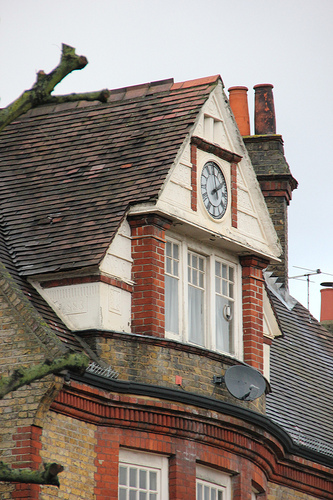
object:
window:
[164, 235, 185, 343]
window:
[195, 475, 226, 499]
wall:
[70, 285, 131, 329]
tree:
[0, 39, 89, 498]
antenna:
[287, 269, 322, 313]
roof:
[264, 288, 333, 459]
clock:
[199, 158, 230, 223]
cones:
[227, 85, 250, 135]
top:
[0, 63, 282, 275]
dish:
[214, 364, 272, 401]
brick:
[133, 259, 151, 280]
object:
[223, 305, 232, 320]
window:
[214, 254, 235, 358]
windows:
[186, 244, 209, 349]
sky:
[0, 1, 331, 321]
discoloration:
[174, 373, 185, 391]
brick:
[176, 441, 195, 460]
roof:
[0, 73, 220, 276]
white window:
[119, 447, 169, 498]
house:
[0, 72, 333, 498]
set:
[163, 234, 242, 363]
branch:
[0, 42, 109, 132]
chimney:
[252, 83, 276, 135]